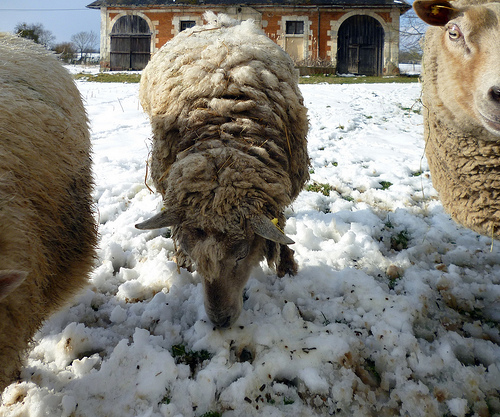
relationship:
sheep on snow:
[131, 6, 334, 330] [2, 58, 498, 416]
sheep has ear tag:
[131, 6, 334, 330] [259, 204, 288, 254]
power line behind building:
[1, 4, 419, 18] [89, 0, 407, 84]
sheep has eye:
[415, 2, 499, 254] [443, 18, 468, 54]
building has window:
[89, 0, 407, 84] [277, 11, 315, 44]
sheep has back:
[131, 6, 334, 330] [142, 17, 318, 159]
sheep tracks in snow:
[345, 178, 425, 304] [2, 58, 498, 416]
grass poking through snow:
[73, 66, 153, 90] [2, 58, 498, 416]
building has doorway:
[89, 0, 407, 84] [330, 6, 400, 83]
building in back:
[89, 0, 407, 84] [3, 4, 497, 84]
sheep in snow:
[131, 6, 334, 330] [2, 58, 498, 416]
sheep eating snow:
[131, 6, 334, 330] [2, 58, 498, 416]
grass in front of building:
[73, 66, 153, 90] [89, 0, 407, 84]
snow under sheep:
[2, 58, 498, 416] [131, 6, 334, 330]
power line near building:
[1, 7, 100, 12] [89, 0, 407, 84]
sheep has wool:
[131, 6, 334, 330] [139, 19, 314, 195]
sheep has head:
[131, 6, 334, 330] [135, 187, 300, 343]